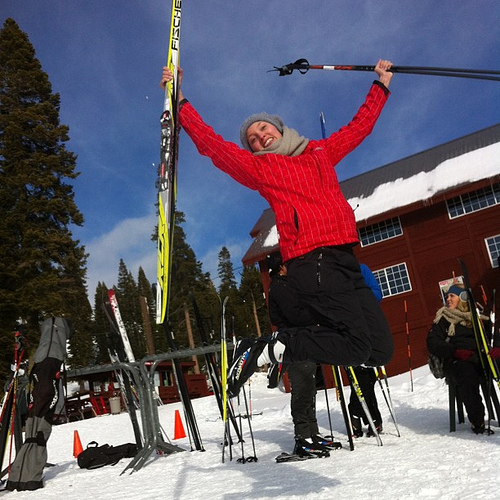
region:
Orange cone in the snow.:
[170, 403, 191, 448]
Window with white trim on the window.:
[434, 192, 498, 223]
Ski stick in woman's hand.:
[145, 3, 187, 331]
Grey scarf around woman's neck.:
[230, 105, 310, 157]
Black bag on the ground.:
[78, 442, 142, 464]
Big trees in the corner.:
[1, 12, 101, 296]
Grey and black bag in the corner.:
[31, 309, 61, 484]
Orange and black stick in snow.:
[392, 286, 426, 400]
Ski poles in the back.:
[200, 283, 255, 493]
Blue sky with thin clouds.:
[212, 2, 416, 42]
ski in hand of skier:
[149, 7, 187, 325]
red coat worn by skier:
[171, 98, 420, 247]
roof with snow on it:
[214, 127, 498, 222]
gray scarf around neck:
[249, 127, 311, 157]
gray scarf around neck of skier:
[434, 302, 479, 334]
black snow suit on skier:
[274, 245, 394, 375]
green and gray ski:
[213, 297, 235, 461]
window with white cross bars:
[363, 257, 417, 300]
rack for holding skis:
[17, 335, 251, 475]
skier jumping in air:
[142, 32, 422, 382]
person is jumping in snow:
[150, 49, 410, 390]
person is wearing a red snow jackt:
[191, 85, 373, 245]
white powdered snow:
[366, 466, 453, 497]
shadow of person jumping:
[187, 448, 337, 497]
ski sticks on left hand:
[271, 45, 498, 90]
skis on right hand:
[149, 17, 213, 319]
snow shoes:
[227, 326, 297, 401]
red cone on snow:
[165, 403, 196, 444]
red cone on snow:
[62, 425, 87, 446]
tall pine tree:
[0, 38, 100, 379]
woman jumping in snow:
[167, 72, 434, 386]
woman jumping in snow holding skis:
[127, 86, 399, 376]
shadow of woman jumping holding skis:
[175, 439, 335, 498]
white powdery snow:
[388, 460, 475, 498]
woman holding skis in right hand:
[135, 13, 210, 337]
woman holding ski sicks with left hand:
[262, 55, 499, 97]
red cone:
[163, 407, 195, 447]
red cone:
[68, 427, 93, 460]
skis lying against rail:
[2, 313, 82, 481]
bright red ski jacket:
[161, 72, 401, 263]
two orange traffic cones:
[62, 407, 195, 461]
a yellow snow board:
[146, 0, 188, 327]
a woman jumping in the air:
[154, 28, 401, 410]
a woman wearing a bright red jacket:
[156, 53, 393, 391]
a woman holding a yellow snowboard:
[122, 3, 398, 382]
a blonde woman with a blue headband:
[425, 278, 497, 446]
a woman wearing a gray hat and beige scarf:
[152, 56, 404, 402]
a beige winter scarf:
[250, 122, 312, 164]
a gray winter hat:
[228, 108, 285, 163]